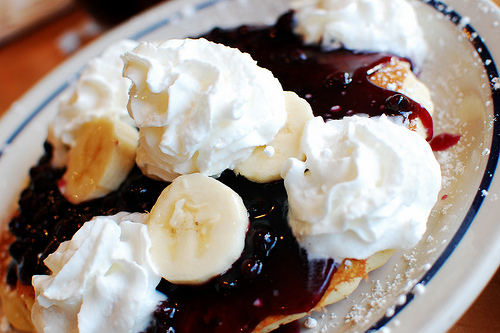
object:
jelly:
[153, 168, 336, 331]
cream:
[29, 209, 167, 331]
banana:
[138, 176, 259, 284]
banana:
[208, 88, 320, 179]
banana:
[52, 117, 139, 197]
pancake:
[0, 30, 423, 331]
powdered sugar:
[382, 62, 422, 98]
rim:
[436, 2, 496, 90]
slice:
[128, 161, 276, 268]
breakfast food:
[13, 52, 420, 287]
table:
[2, 19, 63, 93]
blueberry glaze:
[153, 170, 333, 330]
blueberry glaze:
[11, 195, 68, 239]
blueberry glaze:
[322, 70, 366, 108]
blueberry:
[3, 6, 465, 331]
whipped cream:
[108, 35, 283, 150]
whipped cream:
[28, 218, 171, 331]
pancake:
[383, 62, 428, 97]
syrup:
[282, 53, 360, 101]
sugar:
[302, 232, 455, 332]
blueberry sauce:
[216, 182, 329, 322]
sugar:
[418, 61, 488, 126]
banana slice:
[145, 173, 247, 282]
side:
[256, 255, 363, 330]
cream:
[280, 113, 441, 253]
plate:
[21, 14, 497, 308]